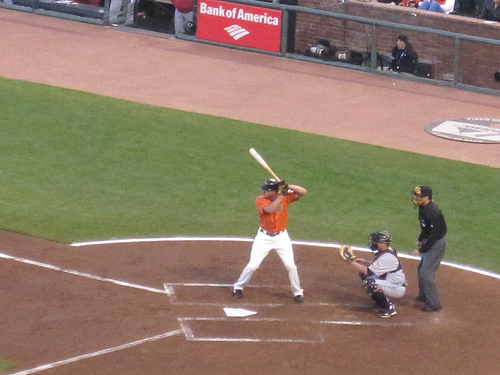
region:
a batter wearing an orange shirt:
[230, 143, 305, 302]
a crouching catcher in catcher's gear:
[337, 230, 406, 319]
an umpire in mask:
[409, 183, 451, 310]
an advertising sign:
[427, 115, 499, 142]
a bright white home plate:
[222, 305, 259, 318]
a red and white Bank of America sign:
[194, 0, 286, 52]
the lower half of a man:
[166, 0, 197, 41]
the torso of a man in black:
[387, 34, 419, 76]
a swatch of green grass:
[0, 76, 499, 280]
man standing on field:
[232, 148, 317, 301]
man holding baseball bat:
[224, 144, 323, 303]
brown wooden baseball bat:
[246, 148, 296, 181]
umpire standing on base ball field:
[407, 186, 454, 318]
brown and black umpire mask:
[403, 187, 438, 208]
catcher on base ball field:
[335, 225, 414, 321]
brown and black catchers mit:
[336, 243, 353, 265]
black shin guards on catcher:
[360, 285, 402, 321]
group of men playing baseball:
[226, 148, 457, 333]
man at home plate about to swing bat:
[223, 142, 318, 331]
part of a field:
[148, 150, 189, 202]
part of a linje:
[198, 280, 238, 330]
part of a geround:
[322, 307, 345, 332]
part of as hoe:
[283, 273, 306, 310]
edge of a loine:
[166, 227, 198, 251]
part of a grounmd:
[101, 287, 135, 327]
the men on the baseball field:
[230, 143, 446, 320]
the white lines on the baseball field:
[0, 236, 499, 373]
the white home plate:
[223, 304, 257, 317]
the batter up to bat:
[232, 147, 308, 304]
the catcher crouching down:
[339, 230, 406, 316]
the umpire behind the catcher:
[409, 182, 449, 311]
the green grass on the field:
[1, 71, 499, 280]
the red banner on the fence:
[196, 0, 283, 50]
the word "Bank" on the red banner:
[199, 3, 226, 19]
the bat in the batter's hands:
[248, 144, 289, 194]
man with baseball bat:
[236, 144, 319, 309]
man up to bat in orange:
[211, 121, 307, 301]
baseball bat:
[247, 140, 287, 195]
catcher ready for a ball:
[336, 217, 409, 312]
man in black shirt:
[408, 182, 462, 316]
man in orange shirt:
[223, 140, 315, 297]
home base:
[216, 301, 264, 338]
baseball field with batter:
[40, 55, 305, 372]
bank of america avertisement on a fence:
[182, 0, 287, 50]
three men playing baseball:
[207, 137, 478, 370]